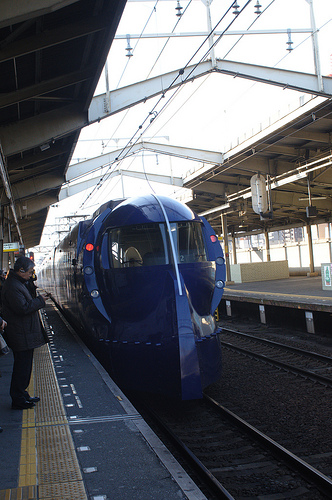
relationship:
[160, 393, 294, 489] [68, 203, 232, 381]
tracks on train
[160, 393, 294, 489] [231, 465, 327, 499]
tracks in front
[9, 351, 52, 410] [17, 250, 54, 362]
legs of man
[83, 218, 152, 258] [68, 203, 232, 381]
window on train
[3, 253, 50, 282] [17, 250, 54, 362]
head of man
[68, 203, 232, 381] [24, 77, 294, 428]
train at station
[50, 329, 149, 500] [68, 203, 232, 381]
platform by train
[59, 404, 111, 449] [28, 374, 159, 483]
spot on sidewalk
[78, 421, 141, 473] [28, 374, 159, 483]
square on sidewalk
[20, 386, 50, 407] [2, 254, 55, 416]
feet on man